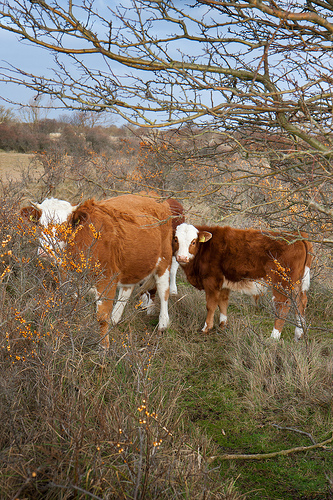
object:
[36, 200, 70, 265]
face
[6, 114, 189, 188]
bush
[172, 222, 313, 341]
calf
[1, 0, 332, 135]
sky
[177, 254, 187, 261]
nose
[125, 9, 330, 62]
branches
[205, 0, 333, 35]
branches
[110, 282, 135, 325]
leg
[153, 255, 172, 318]
leg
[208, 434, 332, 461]
branches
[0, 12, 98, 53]
tree branch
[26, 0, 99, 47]
tree branch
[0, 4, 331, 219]
tree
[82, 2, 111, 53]
branch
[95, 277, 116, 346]
legs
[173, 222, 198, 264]
face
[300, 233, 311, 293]
tail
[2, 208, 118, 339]
leaves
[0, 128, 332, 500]
field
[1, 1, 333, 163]
branches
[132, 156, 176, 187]
flowers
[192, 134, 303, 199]
bare branch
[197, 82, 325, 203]
tree branch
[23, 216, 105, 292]
flowers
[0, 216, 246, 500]
bush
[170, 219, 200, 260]
stripe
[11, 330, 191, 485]
sticks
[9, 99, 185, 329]
tree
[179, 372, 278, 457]
patch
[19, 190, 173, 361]
cow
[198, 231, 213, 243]
ear